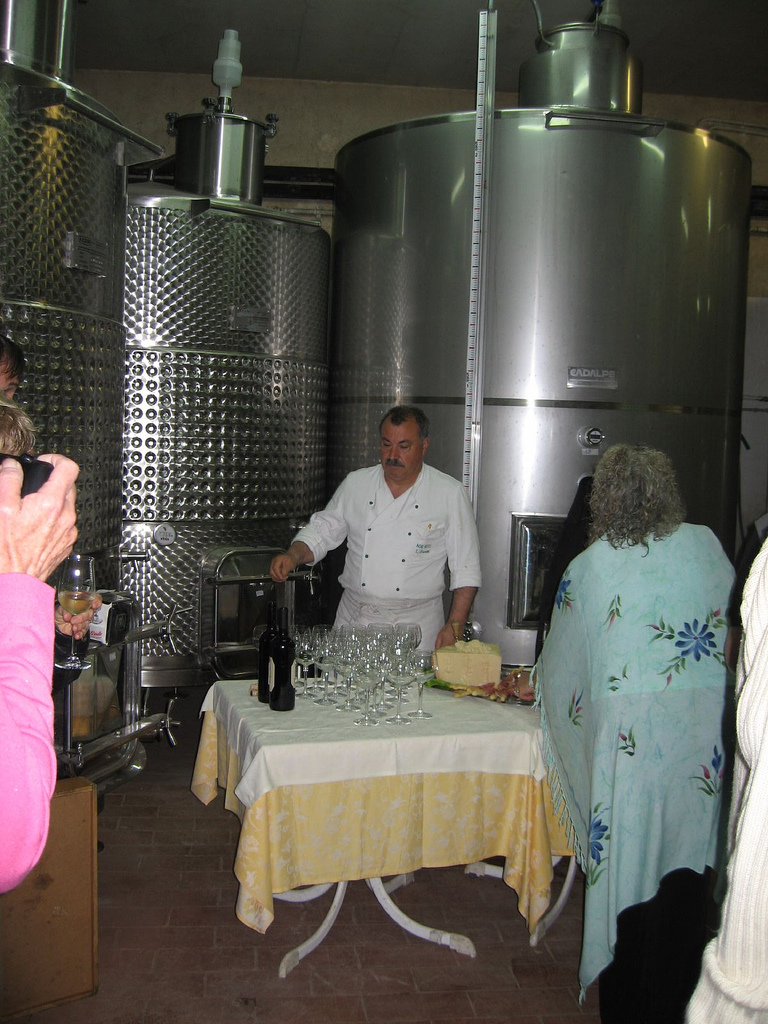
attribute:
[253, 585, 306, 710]
bottles — brown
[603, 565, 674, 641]
caftan — blue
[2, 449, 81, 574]
hand — holding camera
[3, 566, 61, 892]
pink sleeve — of shirt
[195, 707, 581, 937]
table cloth — long , yellow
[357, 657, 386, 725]
vessel — made for drinking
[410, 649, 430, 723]
vessel — made for drinking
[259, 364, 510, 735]
man — looking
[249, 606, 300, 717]
bottles — dark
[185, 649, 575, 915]
table cloth — white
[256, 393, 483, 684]
man — wearing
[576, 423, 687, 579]
hair — grey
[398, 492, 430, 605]
buttons — black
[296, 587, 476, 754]
glasses — empty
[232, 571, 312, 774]
bottles — black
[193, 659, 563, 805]
cloth — white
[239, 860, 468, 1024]
legs — white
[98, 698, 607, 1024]
floor — red, brick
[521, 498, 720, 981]
shaw — blue, floral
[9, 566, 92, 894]
sleeve — pink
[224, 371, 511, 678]
man — grey haired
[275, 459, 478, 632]
coat — white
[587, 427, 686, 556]
hair — curly, grey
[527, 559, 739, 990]
shaw — blue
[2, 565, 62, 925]
sleeve — pink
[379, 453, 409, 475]
mustache — grey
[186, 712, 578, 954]
cloth — yellow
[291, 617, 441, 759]
glasses — empty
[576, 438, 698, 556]
hair — curly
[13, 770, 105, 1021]
box — yellow